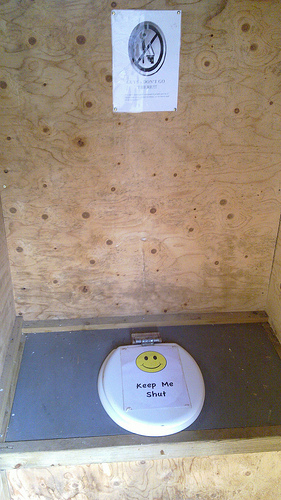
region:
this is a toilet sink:
[101, 346, 197, 419]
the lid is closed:
[105, 348, 192, 426]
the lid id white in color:
[190, 367, 198, 385]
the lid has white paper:
[129, 347, 178, 407]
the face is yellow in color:
[137, 350, 165, 372]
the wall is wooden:
[70, 173, 224, 285]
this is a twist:
[130, 329, 162, 344]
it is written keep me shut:
[133, 376, 176, 400]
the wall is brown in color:
[132, 202, 199, 257]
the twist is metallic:
[130, 330, 161, 344]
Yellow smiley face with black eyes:
[135, 350, 167, 372]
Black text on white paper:
[134, 380, 175, 398]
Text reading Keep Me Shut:
[134, 380, 174, 398]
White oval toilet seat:
[95, 340, 213, 437]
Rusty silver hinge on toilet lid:
[127, 330, 163, 345]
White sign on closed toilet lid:
[100, 331, 204, 435]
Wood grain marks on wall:
[13, 50, 80, 109]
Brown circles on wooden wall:
[233, 16, 263, 58]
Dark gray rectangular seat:
[7, 320, 278, 438]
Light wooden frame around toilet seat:
[1, 310, 279, 468]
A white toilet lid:
[49, 326, 238, 444]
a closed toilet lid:
[78, 326, 225, 453]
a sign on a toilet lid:
[116, 345, 205, 412]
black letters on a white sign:
[119, 373, 191, 404]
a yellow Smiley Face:
[129, 346, 176, 373]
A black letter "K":
[132, 378, 141, 391]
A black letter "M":
[160, 376, 169, 390]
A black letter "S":
[144, 390, 152, 399]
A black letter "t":
[162, 388, 168, 399]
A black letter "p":
[151, 381, 158, 387]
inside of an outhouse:
[6, 9, 262, 481]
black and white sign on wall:
[97, 2, 188, 114]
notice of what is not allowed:
[105, 4, 182, 114]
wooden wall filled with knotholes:
[50, 109, 255, 285]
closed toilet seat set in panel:
[79, 316, 221, 440]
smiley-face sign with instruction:
[113, 333, 191, 413]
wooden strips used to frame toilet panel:
[1, 306, 274, 450]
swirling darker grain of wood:
[52, 455, 261, 490]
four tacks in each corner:
[101, 0, 186, 118]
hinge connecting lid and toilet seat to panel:
[123, 322, 164, 349]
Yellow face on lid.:
[134, 351, 170, 384]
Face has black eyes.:
[133, 345, 159, 364]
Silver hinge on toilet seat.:
[136, 331, 172, 348]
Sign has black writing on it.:
[134, 376, 198, 413]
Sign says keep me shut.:
[130, 374, 199, 408]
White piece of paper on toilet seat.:
[114, 336, 194, 445]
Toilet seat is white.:
[102, 349, 218, 453]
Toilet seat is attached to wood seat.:
[84, 340, 221, 455]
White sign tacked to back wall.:
[80, 26, 198, 147]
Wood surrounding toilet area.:
[73, 175, 272, 274]